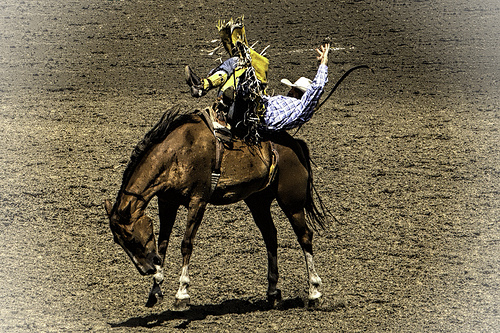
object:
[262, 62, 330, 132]
shirt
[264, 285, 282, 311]
hoof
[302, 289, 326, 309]
hoof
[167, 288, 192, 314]
hoof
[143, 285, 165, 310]
hoof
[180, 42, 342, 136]
cowboy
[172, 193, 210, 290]
leg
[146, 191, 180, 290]
leg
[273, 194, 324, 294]
leg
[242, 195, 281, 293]
leg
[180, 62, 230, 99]
wearing shoes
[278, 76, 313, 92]
hat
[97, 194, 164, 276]
head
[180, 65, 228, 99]
boot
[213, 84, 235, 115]
boot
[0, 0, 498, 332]
dirt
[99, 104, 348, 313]
horse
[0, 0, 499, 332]
arena